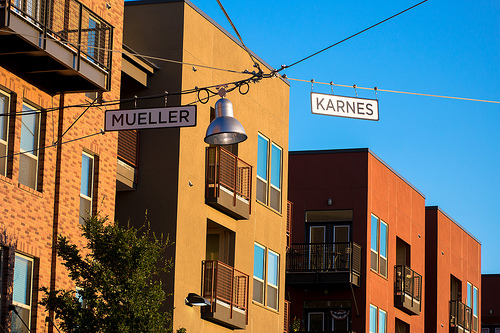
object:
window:
[79, 151, 97, 200]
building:
[0, 1, 290, 333]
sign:
[101, 104, 198, 131]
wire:
[219, 0, 267, 75]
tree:
[39, 210, 188, 333]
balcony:
[201, 258, 250, 331]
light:
[185, 290, 210, 308]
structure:
[287, 148, 484, 333]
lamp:
[203, 97, 250, 146]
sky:
[189, 2, 499, 277]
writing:
[112, 109, 193, 127]